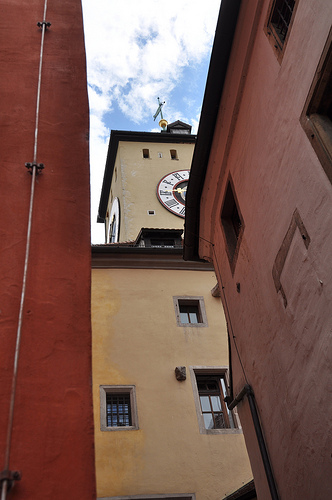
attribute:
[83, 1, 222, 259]
sky — blue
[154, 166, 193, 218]
clock — large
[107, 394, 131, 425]
bars — metal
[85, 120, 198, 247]
tower — steeple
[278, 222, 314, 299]
window — old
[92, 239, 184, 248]
tiles — brown roof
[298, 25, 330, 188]
door frame — wooden